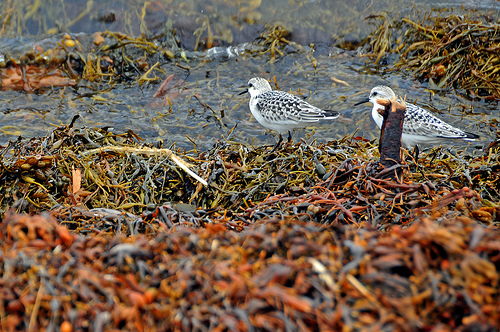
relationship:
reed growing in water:
[190, 90, 219, 113] [2, 1, 484, 153]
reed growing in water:
[212, 64, 221, 85] [2, 1, 484, 153]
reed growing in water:
[152, 72, 173, 98] [2, 1, 484, 153]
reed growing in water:
[137, 60, 162, 85] [2, 1, 484, 153]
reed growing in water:
[327, 73, 351, 86] [2, 1, 484, 153]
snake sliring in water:
[12, 22, 345, 65] [198, 65, 233, 93]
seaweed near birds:
[61, 141, 277, 238] [221, 61, 484, 161]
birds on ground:
[233, 69, 482, 156] [46, 150, 482, 325]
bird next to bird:
[349, 78, 470, 150] [234, 69, 357, 149]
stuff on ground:
[205, 151, 319, 221] [33, 157, 458, 311]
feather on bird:
[456, 123, 486, 156] [351, 72, 491, 154]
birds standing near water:
[236, 75, 341, 160] [137, 62, 250, 132]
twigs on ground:
[40, 139, 270, 264] [21, 143, 470, 325]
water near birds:
[33, 84, 247, 158] [233, 69, 482, 156]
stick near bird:
[374, 96, 411, 171] [351, 82, 481, 160]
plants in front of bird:
[151, 214, 464, 330] [236, 77, 491, 177]